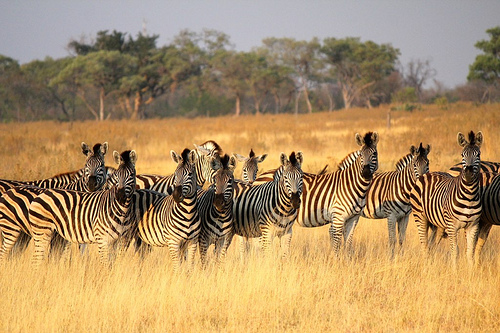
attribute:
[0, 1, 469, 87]
sky — daytime, blue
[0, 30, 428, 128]
leaves — green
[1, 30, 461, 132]
trees — on horizon, green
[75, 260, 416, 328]
grass — dried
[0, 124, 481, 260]
zebras — standing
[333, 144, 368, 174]
mane — black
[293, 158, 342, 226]
torso — zebra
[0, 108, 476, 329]
grass — tall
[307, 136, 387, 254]
zebra — black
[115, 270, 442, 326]
grass — dry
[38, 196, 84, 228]
stripes — white, black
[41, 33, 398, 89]
trees — green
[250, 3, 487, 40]
sky — blue, clear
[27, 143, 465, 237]
animals — black, white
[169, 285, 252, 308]
grass — tall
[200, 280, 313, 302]
grass — yellow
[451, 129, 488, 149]
ears — large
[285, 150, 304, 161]
hair — black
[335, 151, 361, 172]
hair — tall